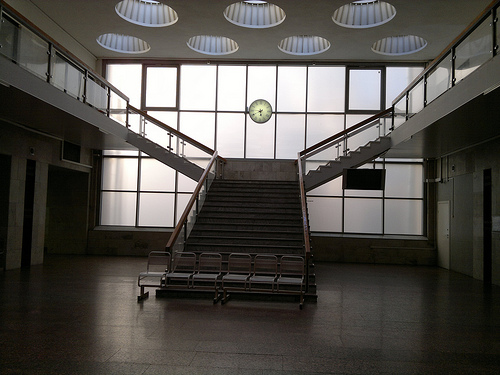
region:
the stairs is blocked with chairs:
[170, 140, 285, 347]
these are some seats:
[141, 248, 315, 301]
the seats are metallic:
[146, 251, 305, 294]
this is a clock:
[244, 97, 277, 125]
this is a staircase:
[208, 169, 295, 254]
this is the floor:
[169, 312, 420, 360]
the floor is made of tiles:
[171, 308, 453, 373]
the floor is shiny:
[54, 253, 141, 355]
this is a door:
[438, 202, 449, 267]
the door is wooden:
[436, 202, 450, 264]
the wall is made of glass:
[184, 82, 217, 122]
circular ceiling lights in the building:
[88, 2, 435, 55]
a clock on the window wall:
[247, 98, 274, 122]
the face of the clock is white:
[248, 96, 271, 124]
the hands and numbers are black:
[246, 95, 272, 124]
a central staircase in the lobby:
[131, 102, 395, 308]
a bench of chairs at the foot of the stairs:
[135, 250, 308, 310]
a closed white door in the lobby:
[432, 197, 457, 273]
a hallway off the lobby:
[41, 164, 91, 267]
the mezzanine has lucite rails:
[0, 3, 499, 200]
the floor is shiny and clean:
[2, 260, 499, 369]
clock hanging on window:
[228, 88, 295, 157]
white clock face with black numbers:
[237, 93, 281, 138]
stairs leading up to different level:
[207, 137, 306, 252]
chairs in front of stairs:
[134, 239, 324, 315]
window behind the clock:
[293, 88, 330, 129]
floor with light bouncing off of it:
[66, 269, 128, 337]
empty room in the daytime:
[59, 38, 445, 368]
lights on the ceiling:
[138, 0, 385, 72]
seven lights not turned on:
[108, 8, 433, 85]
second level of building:
[18, 29, 109, 91]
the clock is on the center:
[199, 94, 319, 141]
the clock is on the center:
[217, 98, 282, 145]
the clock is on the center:
[229, 67, 304, 161]